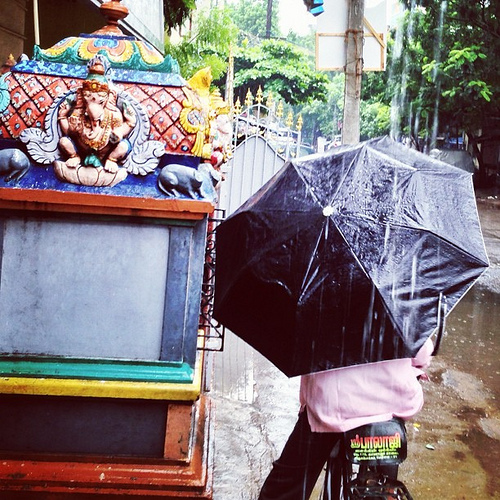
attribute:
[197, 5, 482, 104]
trees — tall, green